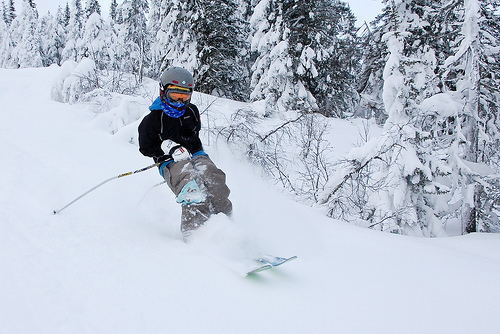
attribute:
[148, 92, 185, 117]
bandana — blue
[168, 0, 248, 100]
tree — pine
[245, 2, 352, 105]
tree — pine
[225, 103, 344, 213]
brush — small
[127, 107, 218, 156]
jacket — black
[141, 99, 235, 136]
scarf — blue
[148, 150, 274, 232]
pants — grey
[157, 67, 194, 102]
helmet — grey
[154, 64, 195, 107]
helmet — gray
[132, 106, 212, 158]
jacket — black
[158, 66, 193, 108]
helmet — grey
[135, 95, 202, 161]
sweatshirt — blue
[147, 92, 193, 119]
hankerchief — blue